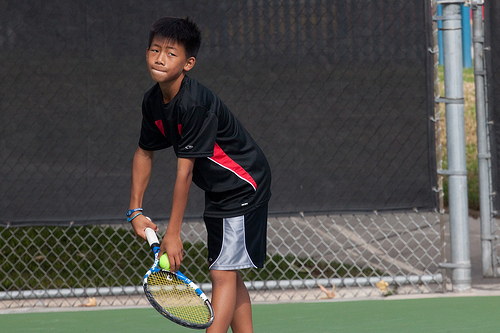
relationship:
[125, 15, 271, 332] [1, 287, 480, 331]
boy on court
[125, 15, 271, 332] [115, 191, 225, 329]
boy holding racket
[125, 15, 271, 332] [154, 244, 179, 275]
boy holding ball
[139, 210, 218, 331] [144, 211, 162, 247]
racquet has handle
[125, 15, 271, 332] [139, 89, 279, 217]
boy wearing t-shirt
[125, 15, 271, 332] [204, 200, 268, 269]
boy wearing shorts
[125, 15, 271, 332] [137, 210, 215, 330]
boy holding racket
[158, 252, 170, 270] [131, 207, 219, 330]
ball on top of racket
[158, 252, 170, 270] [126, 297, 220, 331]
ball on top of racket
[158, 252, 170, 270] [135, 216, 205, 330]
ball on top of racket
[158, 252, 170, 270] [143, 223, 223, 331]
ball on top of racket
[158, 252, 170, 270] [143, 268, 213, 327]
ball on top of racket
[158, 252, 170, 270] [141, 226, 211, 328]
ball on top of racket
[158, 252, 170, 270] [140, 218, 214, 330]
ball on top of racket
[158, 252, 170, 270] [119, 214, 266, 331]
ball on top of racket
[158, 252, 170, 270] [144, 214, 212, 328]
ball on top of racket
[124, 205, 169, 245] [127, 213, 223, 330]
handle of racket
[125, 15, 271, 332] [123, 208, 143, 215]
boy wearing bracelet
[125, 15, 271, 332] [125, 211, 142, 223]
boy wearing bracelet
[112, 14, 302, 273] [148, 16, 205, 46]
boy with hair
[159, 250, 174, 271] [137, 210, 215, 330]
ball on racket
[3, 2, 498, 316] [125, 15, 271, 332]
fence behind boy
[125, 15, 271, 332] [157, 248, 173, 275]
boy about to serve ball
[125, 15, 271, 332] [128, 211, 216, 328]
boy holding racket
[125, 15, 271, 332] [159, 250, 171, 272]
boy holding ball